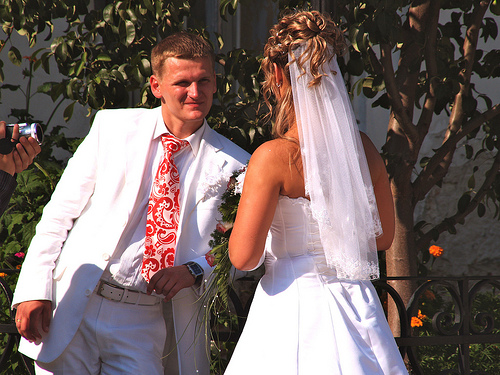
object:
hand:
[15, 299, 53, 341]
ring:
[14, 319, 19, 322]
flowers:
[407, 242, 445, 327]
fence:
[369, 271, 499, 374]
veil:
[287, 43, 385, 281]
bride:
[223, 24, 411, 374]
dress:
[223, 196, 411, 374]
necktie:
[141, 134, 189, 292]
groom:
[10, 34, 252, 374]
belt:
[97, 279, 160, 306]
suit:
[11, 96, 251, 366]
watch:
[183, 261, 204, 288]